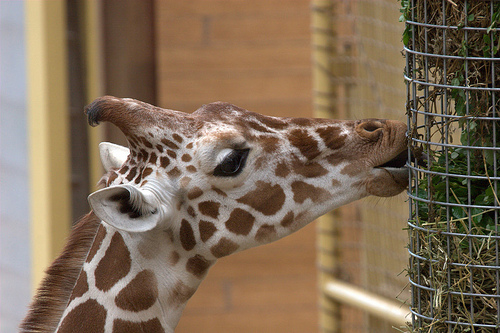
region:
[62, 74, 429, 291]
the giraffe is eating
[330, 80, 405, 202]
mouth of the giraffe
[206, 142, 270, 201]
eye of the giraffe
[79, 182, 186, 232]
ear of the giraffe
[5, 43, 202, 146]
horn on the girafe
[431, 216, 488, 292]
hay in the holder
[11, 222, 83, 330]
mane of the girafe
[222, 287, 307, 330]
the wall is blurred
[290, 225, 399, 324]
the enclosure is blurred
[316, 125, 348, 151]
brown spot on giraffe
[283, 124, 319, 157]
brown spot on giraffe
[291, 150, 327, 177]
brown spot on giraffe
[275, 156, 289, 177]
brown spot on giraffe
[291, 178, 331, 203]
brown spot on giraffe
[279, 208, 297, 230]
brown spot on giraffe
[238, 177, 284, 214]
brown spot on giraffe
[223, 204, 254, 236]
brown spot on giraffe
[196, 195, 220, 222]
brown spot on giraffe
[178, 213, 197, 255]
brown spot on giraffe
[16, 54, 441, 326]
giraffe feeding from feeder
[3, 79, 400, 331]
giraffe reaching into feeder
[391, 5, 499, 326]
feeder with plants in it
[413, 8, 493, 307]
plants in the feeder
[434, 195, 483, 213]
wire structure of the feeder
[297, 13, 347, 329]
pole to wire structure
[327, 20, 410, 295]
wire enclosure to an area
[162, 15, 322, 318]
brick wall behind giraffe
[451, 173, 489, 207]
leaves that are green in feeder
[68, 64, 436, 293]
head of a giraffe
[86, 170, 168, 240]
ear of a giraffe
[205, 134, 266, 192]
an eye of a giraffe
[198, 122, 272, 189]
eye of a giraffe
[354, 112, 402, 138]
nose of a giraffe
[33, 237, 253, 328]
neck of a giraffe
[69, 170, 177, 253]
an ear of a giraffe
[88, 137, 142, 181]
ear of a giraffe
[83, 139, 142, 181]
an ear of a giraffe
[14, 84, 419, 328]
This is a giraffe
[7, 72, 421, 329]
This is a giraffe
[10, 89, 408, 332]
large brown spotted giraffe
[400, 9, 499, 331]
large wired metal container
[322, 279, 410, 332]
long thick metal pole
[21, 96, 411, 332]
large long brown and white giraffe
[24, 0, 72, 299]
tall long yellow paint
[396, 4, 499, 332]
large silver metal wire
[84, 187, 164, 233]
large white giraffe ear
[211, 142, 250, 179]
large almond black eye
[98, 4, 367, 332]
large tall open door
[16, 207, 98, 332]
long short brown hair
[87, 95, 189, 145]
short round bone horn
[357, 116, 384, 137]
small round nose hole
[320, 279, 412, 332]
long round metal pole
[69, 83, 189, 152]
horns on giraffe's head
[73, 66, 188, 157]
horns on giraffe's head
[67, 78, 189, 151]
horns on giraffe's head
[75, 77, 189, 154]
horns on giraffe's head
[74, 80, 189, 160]
horns on giraffe's head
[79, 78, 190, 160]
horns on giraffe's head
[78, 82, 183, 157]
horns on giraffe's head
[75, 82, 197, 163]
horns on giraffe's head